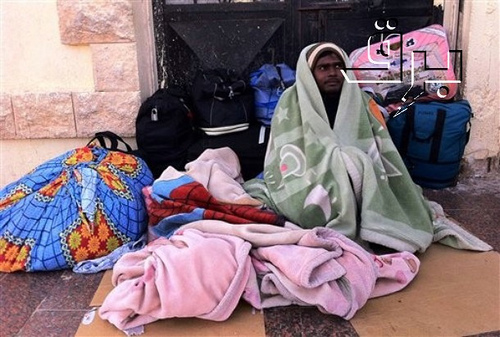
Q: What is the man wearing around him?
A: Blanket.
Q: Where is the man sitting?
A: Sidewalk.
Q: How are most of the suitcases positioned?
A: Behind the man.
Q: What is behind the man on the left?
A: Wall.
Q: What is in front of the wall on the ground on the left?
A: Blue bag with floral design and black handles.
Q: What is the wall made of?
A: Brick and mortar.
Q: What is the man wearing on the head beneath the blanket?
A: Hat.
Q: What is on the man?
A: A blanket.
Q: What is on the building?
A: Bricks.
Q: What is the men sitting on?
A: Cardboard.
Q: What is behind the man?
A: Luggage.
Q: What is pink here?
A: Blankets.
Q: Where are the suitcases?
A: Behind the man.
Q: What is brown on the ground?
A: Cardboard.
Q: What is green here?
A: A blanket.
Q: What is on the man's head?
A: A beanie.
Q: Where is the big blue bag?
A: Next to the man.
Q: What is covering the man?
A: Green blanket.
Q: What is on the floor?
A: Clothes.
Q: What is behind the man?
A: Bags.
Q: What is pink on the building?
A: Wall.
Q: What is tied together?
A: Clothing pile.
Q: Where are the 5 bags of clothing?
A: On ground.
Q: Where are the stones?
A: On wall.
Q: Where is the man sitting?
A: On floor.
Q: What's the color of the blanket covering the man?
A: Green.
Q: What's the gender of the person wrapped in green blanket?
A: Male.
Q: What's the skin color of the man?
A: Brown.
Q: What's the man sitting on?
A: Cardboard.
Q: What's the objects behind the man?
A: Bags.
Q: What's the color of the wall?
A: Beige.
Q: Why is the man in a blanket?
A: He is cold.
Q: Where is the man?
A: On a sidewalk.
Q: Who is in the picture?
A: A man.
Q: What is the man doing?
A: Sitting on the ground.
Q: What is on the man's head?
A: A blanket.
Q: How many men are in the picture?
A: One.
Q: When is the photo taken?
A: During the day.